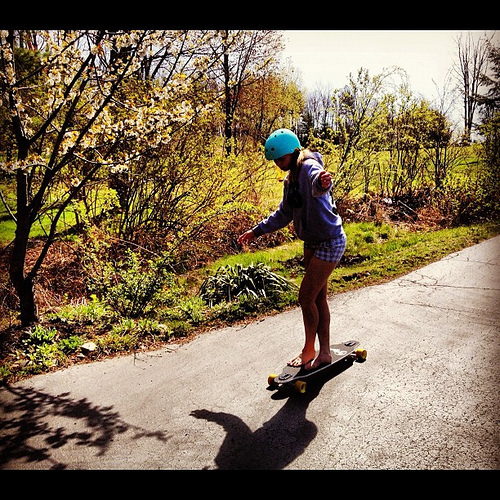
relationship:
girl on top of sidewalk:
[236, 126, 348, 369] [1, 230, 497, 470]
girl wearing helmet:
[236, 126, 348, 369] [263, 129, 303, 156]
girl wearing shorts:
[236, 126, 348, 369] [302, 234, 348, 263]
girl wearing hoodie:
[236, 126, 348, 369] [252, 152, 345, 241]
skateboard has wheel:
[268, 339, 368, 396] [354, 345, 369, 362]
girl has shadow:
[236, 126, 348, 369] [189, 385, 323, 471]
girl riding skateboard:
[236, 126, 348, 369] [268, 339, 368, 396]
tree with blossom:
[1, 29, 224, 324] [73, 177, 82, 190]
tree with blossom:
[1, 29, 224, 324] [109, 164, 129, 174]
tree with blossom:
[1, 29, 224, 324] [157, 134, 171, 144]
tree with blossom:
[1, 29, 224, 324] [173, 101, 193, 125]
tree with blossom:
[1, 29, 224, 324] [135, 117, 157, 134]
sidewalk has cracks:
[1, 230, 497, 470] [396, 271, 500, 298]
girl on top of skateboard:
[236, 126, 348, 369] [268, 339, 368, 396]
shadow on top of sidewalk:
[189, 385, 323, 471] [1, 230, 497, 470]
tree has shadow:
[1, 29, 224, 324] [1, 380, 174, 470]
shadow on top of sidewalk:
[1, 380, 174, 470] [1, 230, 497, 470]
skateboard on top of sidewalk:
[268, 339, 368, 396] [1, 230, 497, 470]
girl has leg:
[236, 126, 348, 369] [287, 260, 343, 368]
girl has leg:
[236, 126, 348, 369] [303, 241, 332, 372]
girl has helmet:
[236, 126, 348, 369] [263, 129, 303, 156]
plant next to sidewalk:
[197, 261, 301, 305] [1, 230, 497, 470]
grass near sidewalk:
[41, 221, 498, 328] [1, 230, 497, 470]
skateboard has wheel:
[268, 339, 368, 396] [294, 378, 309, 397]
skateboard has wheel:
[268, 339, 368, 396] [267, 373, 278, 386]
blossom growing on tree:
[73, 177, 82, 190] [1, 29, 224, 324]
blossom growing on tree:
[109, 164, 129, 174] [1, 29, 224, 324]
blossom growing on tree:
[157, 134, 171, 144] [1, 29, 224, 324]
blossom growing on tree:
[173, 101, 193, 125] [1, 29, 224, 324]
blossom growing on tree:
[135, 117, 157, 134] [1, 29, 224, 324]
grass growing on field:
[41, 221, 498, 328] [1, 146, 499, 385]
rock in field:
[79, 342, 99, 356] [1, 146, 499, 385]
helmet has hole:
[263, 129, 303, 156] [269, 146, 275, 153]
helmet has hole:
[263, 129, 303, 156] [263, 147, 270, 154]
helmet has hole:
[263, 129, 303, 156] [281, 130, 286, 136]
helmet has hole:
[263, 129, 303, 156] [272, 132, 279, 139]